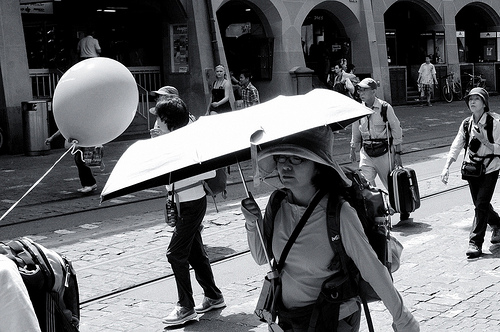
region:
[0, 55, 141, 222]
a balloon floating on a string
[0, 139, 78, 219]
a string holding a balloon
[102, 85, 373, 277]
a ladies umbrella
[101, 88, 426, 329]
a young lady holding an umbrella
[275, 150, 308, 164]
a woman's eye glasses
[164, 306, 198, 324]
a woman's left shoe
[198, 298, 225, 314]
a woman's right shoe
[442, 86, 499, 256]
a woman wearing a hat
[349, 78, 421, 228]
a man carrying a suitcase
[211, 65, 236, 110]
a woman wearing a dress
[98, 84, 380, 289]
Woman holding an umbrella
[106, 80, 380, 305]
Woman is holding an umbrella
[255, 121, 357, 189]
Woman wearing a hat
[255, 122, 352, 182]
Woman is wearing a hat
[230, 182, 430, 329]
Woman wearing a shirt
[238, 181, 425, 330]
Woman is wearing a shirt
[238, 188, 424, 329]
Woman wearing a long sleeved shirt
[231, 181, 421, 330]
Woman is wearing a long sleeved shirt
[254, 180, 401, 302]
Woman wearing a backpack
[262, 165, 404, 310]
Woman is wearing a backpack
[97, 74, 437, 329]
woman carries odd flattish umbrella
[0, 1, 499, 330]
scene is greyscale, in an asian country, but which i cannot tname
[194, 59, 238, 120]
tall woman wears short dress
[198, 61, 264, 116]
tall woman in short black dress pestered by small man in plaid shirt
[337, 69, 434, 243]
middle aged man wears bellypack, carries modular suitcase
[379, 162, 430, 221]
suitcase is made of heavy plastic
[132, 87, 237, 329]
woman wears flat sneakers, in a lighter colour than her pants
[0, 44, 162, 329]
pack animal burdened by balloon -or- human being bending down w/ balloon in background. difficult to tell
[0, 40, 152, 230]
balloon on a string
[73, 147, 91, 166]
end of string is curly swirly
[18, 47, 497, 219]
People walking pass a building.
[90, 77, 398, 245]
a person holding an umbrella.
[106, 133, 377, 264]
A person under an umbrella.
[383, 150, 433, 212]
A person carrying a suitcase.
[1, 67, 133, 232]
a person holding a balloon.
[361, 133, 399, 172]
A person wearing a fannypack.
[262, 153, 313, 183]
A woman wearing eyeglasses.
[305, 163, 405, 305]
A woman carrying a backpack.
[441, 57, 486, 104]
Bikes parked outside a building.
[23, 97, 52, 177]
A trashcan standing next to stairs.